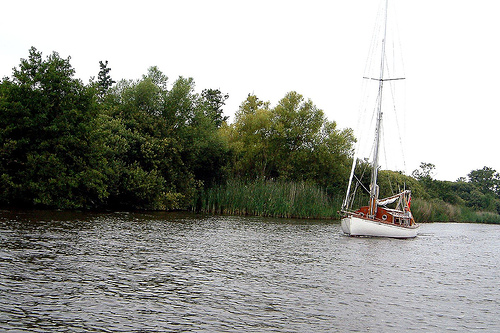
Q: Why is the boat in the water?
A: To fish.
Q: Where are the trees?
A: On the riverbank.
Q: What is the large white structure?
A: Flagpole.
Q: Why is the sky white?
A: Hazy.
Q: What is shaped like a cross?
A: Mast.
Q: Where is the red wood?
A: On the boat.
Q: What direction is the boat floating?
A: Forward.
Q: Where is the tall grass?
A: In front of the trees.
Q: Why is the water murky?
A: Mud.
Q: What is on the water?
A: A boat.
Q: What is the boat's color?
A: Red and white.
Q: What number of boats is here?
A: 1.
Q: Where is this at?
A: A river.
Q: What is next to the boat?
A: Trees.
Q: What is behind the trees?
A: A sky.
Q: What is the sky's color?
A: White.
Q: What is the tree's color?
A: Green.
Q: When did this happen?
A: During the day time.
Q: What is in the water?
A: A sailboat.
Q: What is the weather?
A: Cloudy skies.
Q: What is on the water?
A: A boat.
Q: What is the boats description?
A: Red and white.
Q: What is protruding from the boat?
A: A long mast.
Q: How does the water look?
A: It looks gray.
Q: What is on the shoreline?
A: Trees.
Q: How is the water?
A: The water is calm.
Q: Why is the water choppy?
A: Wind.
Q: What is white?
A: Boat.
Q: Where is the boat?
A: Lake.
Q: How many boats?
A: One.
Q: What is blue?
A: Sky.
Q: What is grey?
A: The staff on the boat.